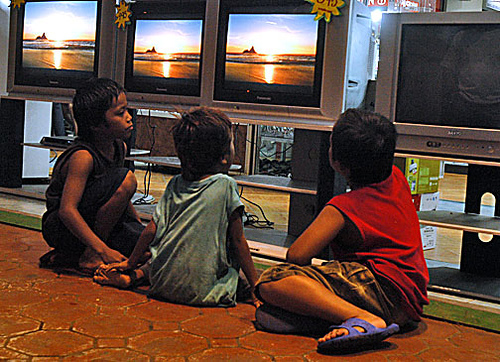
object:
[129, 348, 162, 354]
brick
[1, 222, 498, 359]
floor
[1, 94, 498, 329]
shelves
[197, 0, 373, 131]
televisions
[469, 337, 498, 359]
stone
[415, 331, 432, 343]
stone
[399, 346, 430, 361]
brick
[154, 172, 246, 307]
shirt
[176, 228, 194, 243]
green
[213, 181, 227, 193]
green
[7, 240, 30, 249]
brick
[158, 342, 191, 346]
brick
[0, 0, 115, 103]
tv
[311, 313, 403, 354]
sandal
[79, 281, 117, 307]
stone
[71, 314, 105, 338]
brick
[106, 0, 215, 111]
televisions.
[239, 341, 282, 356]
brick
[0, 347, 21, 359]
brick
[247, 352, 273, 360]
brick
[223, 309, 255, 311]
brick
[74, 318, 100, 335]
brick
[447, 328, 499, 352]
brick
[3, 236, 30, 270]
brick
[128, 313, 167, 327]
red brick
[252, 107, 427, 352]
boy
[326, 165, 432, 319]
red shirt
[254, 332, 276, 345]
red stone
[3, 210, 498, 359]
ground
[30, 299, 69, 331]
red stone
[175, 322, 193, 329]
brick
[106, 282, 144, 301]
red stone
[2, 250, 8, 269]
stone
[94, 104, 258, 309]
boy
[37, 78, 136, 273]
boy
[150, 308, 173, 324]
brick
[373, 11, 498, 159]
television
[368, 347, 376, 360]
stone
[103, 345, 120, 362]
stone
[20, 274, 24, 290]
brick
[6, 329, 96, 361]
tiles